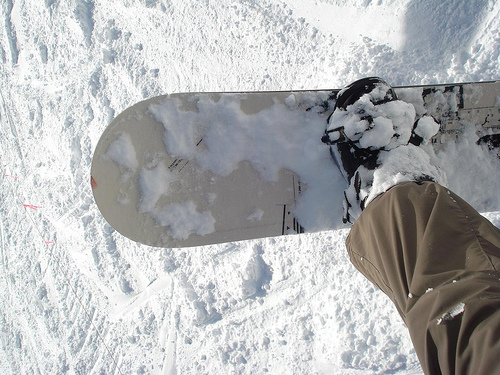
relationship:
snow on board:
[107, 86, 500, 246] [96, 96, 498, 242]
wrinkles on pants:
[346, 183, 462, 301] [343, 172, 497, 372]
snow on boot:
[312, 86, 459, 243] [325, 76, 439, 212]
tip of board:
[91, 90, 187, 248] [56, 98, 495, 223]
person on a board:
[322, 77, 500, 375] [91, 79, 500, 248]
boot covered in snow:
[329, 74, 439, 204] [1, 3, 498, 374]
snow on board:
[85, 78, 482, 248] [91, 79, 500, 248]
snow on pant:
[1, 3, 498, 374] [345, 180, 497, 374]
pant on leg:
[345, 180, 497, 374] [352, 157, 498, 368]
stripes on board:
[282, 94, 471, 232] [91, 79, 500, 248]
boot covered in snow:
[325, 76, 439, 212] [1, 3, 498, 374]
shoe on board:
[321, 72, 439, 225] [91, 79, 500, 248]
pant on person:
[345, 180, 500, 375] [322, 77, 500, 375]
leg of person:
[352, 157, 498, 368] [322, 77, 500, 375]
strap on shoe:
[322, 108, 435, 142] [321, 77, 439, 224]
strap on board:
[322, 108, 435, 142] [91, 79, 500, 248]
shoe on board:
[321, 77, 439, 224] [91, 79, 500, 248]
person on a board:
[332, 111, 499, 368] [91, 79, 500, 248]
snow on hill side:
[1, 3, 498, 374] [1, 0, 498, 372]